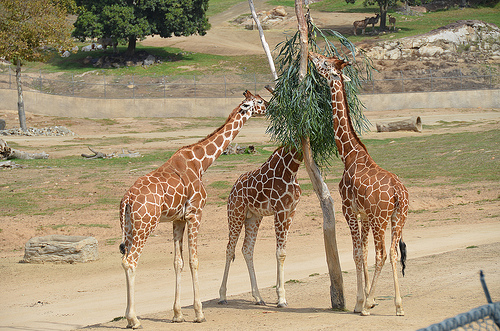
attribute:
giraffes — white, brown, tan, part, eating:
[116, 89, 276, 324]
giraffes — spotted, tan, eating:
[218, 113, 305, 306]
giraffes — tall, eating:
[308, 51, 411, 315]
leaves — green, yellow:
[1, 0, 78, 66]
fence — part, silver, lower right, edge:
[395, 301, 497, 330]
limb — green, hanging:
[264, 5, 373, 176]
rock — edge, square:
[20, 233, 99, 264]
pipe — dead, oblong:
[374, 117, 425, 133]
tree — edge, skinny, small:
[1, 2, 80, 134]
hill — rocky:
[349, 22, 498, 71]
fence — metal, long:
[1, 72, 500, 99]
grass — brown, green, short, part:
[1, 128, 500, 211]